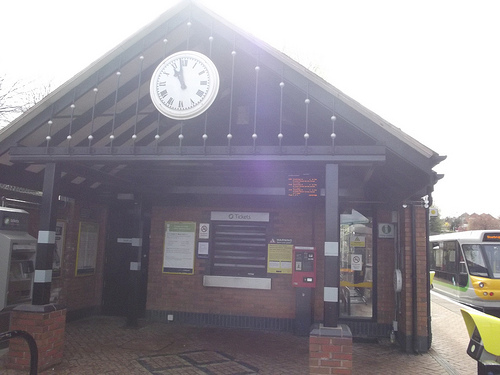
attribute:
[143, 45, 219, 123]
clock — inner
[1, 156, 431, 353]
building — brick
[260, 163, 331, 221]
sign — updated, electric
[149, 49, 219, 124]
clock — white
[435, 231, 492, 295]
train — white , yellow 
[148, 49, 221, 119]
clock — black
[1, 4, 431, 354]
bus terminal — wood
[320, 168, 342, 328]
column — wood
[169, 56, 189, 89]
dial — black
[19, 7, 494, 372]
platform — railway, station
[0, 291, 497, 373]
floor — bricks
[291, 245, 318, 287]
machine — red 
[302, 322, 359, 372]
bricks — red, bricked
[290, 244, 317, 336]
machine — ticket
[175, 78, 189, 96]
circle — black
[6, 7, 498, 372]
station — rail, train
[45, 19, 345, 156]
bars — metal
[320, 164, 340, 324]
bar — metal, black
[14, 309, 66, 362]
brick — red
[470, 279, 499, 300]
bumper — yellow